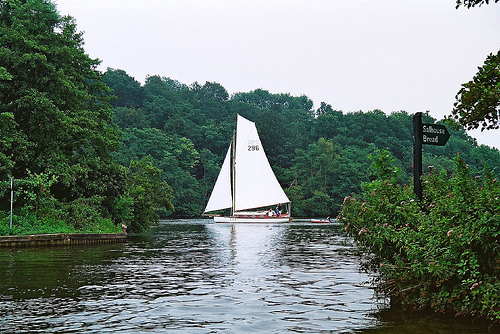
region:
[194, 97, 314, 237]
boat with sail flag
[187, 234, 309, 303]
the water is calm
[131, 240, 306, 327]
the water is calm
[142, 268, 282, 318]
the water is calm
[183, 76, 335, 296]
a boat in the water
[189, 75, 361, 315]
a sailboat in the water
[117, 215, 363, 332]
a body of water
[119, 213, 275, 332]
a body of calm water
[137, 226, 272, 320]
a body of water that is calm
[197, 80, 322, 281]
a boat with white sail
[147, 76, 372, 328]
a sailboat with white sail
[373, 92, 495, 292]
a sign on a pole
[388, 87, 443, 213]
a sign on a wooden pole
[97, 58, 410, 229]
green leaves on a tree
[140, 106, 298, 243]
white sail boat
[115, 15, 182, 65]
white clouds in blue sky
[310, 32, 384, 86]
white clouds in blue sky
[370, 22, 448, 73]
white clouds in blue sky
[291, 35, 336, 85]
white clouds in blue sky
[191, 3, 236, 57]
white clouds in blue sky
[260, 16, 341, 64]
white clouds in blue sky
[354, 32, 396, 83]
white clouds in blue sky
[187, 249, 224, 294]
part of a water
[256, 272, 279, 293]
part of a water